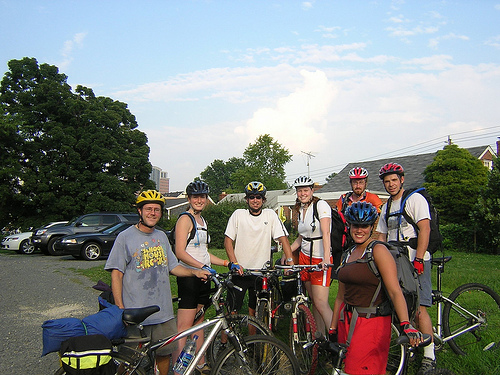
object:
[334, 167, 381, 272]
people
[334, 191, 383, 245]
shirt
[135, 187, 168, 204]
helmets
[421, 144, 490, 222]
tree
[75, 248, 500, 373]
grass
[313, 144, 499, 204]
building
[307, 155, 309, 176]
telephone pole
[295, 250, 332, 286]
shorts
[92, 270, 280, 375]
bicycle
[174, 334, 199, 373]
water bottle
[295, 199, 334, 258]
shirt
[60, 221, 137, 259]
vehicles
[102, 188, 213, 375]
people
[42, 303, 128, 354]
bundle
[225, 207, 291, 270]
tee shirt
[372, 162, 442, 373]
man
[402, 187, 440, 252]
backpack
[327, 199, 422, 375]
young lady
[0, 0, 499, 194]
sky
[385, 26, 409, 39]
clouds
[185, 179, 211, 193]
helmet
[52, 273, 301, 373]
bicycles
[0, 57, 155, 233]
trees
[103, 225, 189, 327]
shirt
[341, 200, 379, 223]
helmet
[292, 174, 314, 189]
helmet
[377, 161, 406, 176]
helmet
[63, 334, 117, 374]
bag